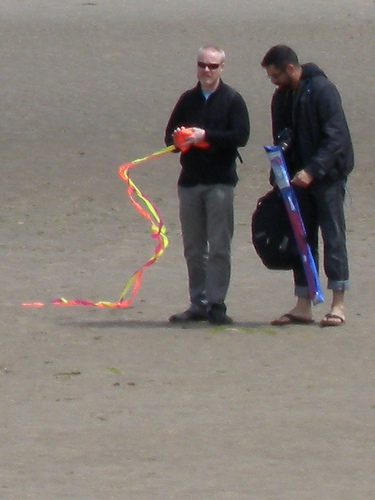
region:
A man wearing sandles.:
[263, 275, 351, 331]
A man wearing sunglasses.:
[180, 49, 223, 79]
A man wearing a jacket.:
[257, 71, 348, 179]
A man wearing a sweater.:
[131, 75, 254, 197]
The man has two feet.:
[261, 274, 345, 330]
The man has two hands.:
[166, 116, 208, 153]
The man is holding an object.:
[146, 111, 214, 156]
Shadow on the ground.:
[53, 300, 161, 340]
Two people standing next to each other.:
[126, 7, 354, 334]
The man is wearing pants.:
[161, 170, 250, 311]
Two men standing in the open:
[160, 42, 347, 325]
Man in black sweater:
[162, 42, 248, 321]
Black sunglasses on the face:
[195, 60, 219, 70]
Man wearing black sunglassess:
[161, 41, 233, 320]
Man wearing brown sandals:
[256, 43, 354, 325]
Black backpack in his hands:
[250, 176, 319, 270]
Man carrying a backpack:
[255, 40, 357, 325]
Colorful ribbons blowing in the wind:
[17, 125, 204, 327]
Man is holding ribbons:
[17, 39, 252, 328]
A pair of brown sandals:
[269, 297, 354, 331]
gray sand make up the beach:
[278, 420, 373, 485]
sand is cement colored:
[21, 183, 138, 293]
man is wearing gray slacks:
[182, 181, 234, 295]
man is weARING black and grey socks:
[156, 295, 264, 332]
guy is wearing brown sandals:
[270, 300, 350, 345]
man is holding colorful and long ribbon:
[117, 114, 182, 335]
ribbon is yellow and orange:
[115, 159, 165, 309]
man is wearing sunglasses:
[198, 38, 215, 77]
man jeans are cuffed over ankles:
[270, 258, 364, 296]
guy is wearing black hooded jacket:
[250, 56, 373, 221]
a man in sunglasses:
[186, 38, 235, 101]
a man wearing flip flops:
[256, 157, 372, 346]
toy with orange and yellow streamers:
[9, 104, 274, 329]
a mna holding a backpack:
[242, 38, 374, 329]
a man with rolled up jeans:
[248, 42, 366, 335]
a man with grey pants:
[142, 31, 265, 329]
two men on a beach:
[114, 27, 373, 359]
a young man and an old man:
[119, 34, 362, 337]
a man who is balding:
[143, 33, 276, 183]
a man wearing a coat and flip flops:
[246, 37, 371, 351]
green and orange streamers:
[52, 145, 163, 335]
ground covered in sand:
[85, 366, 282, 480]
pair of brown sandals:
[270, 306, 345, 331]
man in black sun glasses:
[187, 42, 223, 89]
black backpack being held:
[247, 180, 288, 272]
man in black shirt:
[142, 30, 247, 189]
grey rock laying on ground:
[11, 212, 29, 238]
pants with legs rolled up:
[276, 182, 360, 303]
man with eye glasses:
[251, 36, 308, 95]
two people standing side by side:
[116, 23, 370, 345]